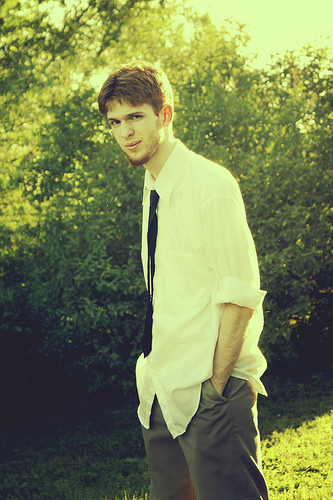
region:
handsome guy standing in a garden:
[92, 68, 259, 498]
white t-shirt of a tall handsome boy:
[140, 157, 265, 428]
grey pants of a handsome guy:
[144, 379, 263, 491]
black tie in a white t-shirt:
[144, 192, 159, 348]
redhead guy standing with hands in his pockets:
[95, 65, 268, 497]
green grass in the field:
[0, 367, 330, 494]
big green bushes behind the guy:
[4, 18, 332, 368]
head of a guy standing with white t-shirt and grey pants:
[104, 60, 169, 164]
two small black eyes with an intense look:
[105, 108, 146, 125]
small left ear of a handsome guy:
[161, 104, 176, 126]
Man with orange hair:
[93, 58, 276, 497]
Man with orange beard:
[95, 57, 265, 498]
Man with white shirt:
[96, 60, 272, 498]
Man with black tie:
[98, 60, 269, 496]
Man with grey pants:
[96, 64, 273, 497]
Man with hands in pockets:
[96, 60, 271, 497]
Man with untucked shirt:
[100, 60, 273, 498]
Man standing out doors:
[96, 63, 272, 498]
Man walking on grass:
[97, 63, 272, 497]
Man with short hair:
[96, 56, 271, 496]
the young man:
[94, 60, 283, 496]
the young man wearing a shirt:
[81, 49, 288, 498]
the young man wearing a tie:
[73, 43, 295, 499]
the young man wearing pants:
[89, 51, 294, 495]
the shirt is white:
[126, 153, 277, 436]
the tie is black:
[130, 185, 187, 359]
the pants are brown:
[115, 372, 287, 499]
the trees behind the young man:
[4, 4, 320, 404]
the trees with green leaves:
[7, 7, 327, 356]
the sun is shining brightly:
[250, 11, 297, 47]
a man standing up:
[39, 19, 276, 385]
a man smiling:
[57, 54, 321, 347]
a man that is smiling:
[63, 56, 239, 189]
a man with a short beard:
[54, 19, 306, 294]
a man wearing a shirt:
[57, 34, 294, 331]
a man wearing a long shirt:
[49, 52, 317, 437]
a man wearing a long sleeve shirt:
[55, 33, 306, 371]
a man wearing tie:
[78, 50, 319, 349]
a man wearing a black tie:
[78, 45, 313, 383]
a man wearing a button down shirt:
[81, 42, 302, 361]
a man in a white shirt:
[61, 30, 309, 378]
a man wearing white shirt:
[74, 56, 324, 430]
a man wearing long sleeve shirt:
[69, 38, 331, 343]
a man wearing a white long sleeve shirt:
[60, 22, 292, 378]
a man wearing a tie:
[76, 59, 249, 335]